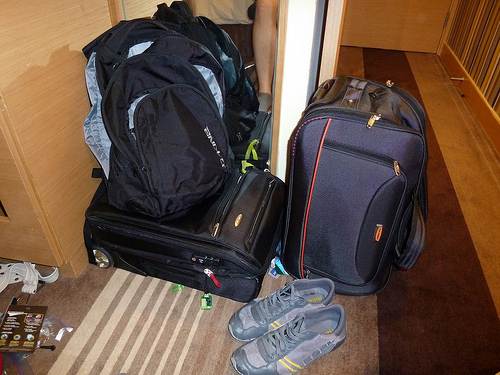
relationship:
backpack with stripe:
[276, 76, 429, 298] [294, 119, 335, 283]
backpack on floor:
[276, 76, 429, 298] [5, 35, 497, 373]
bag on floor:
[81, 152, 288, 303] [5, 35, 497, 373]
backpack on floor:
[84, 17, 236, 223] [5, 35, 497, 373]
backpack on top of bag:
[84, 17, 236, 223] [82, 167, 287, 302]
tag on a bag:
[197, 290, 219, 311] [81, 152, 288, 303]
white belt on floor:
[0, 256, 62, 299] [5, 35, 497, 373]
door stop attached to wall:
[445, 65, 467, 85] [432, 5, 497, 158]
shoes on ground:
[257, 272, 337, 356] [9, 46, 498, 373]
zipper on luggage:
[390, 161, 400, 178] [290, 68, 439, 298]